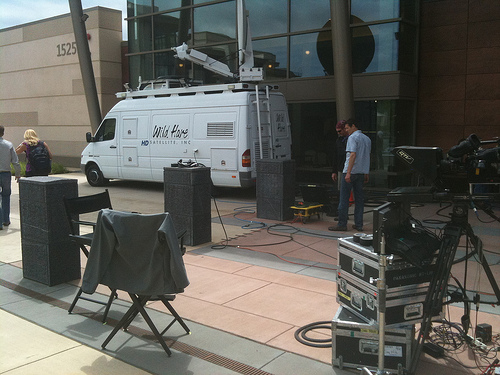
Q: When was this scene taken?
A: Yesterday.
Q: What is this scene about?
A: A movie shoot.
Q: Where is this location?
A: London.